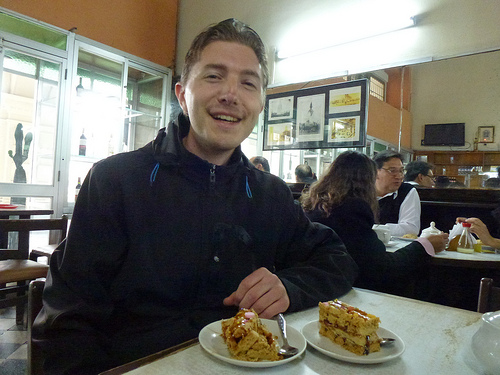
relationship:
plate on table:
[388, 348, 408, 368] [98, 286, 498, 373]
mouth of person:
[207, 108, 245, 125] [27, 19, 355, 375]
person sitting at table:
[97, 25, 332, 294] [397, 296, 442, 342]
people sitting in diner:
[42, 17, 354, 374] [4, 5, 484, 362]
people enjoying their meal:
[298, 149, 449, 278] [195, 296, 400, 374]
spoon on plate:
[274, 312, 298, 358] [195, 313, 305, 367]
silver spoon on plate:
[375, 325, 394, 347] [298, 303, 408, 365]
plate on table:
[195, 313, 305, 367] [98, 286, 498, 373]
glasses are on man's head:
[366, 159, 420, 181] [375, 151, 408, 200]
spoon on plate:
[274, 312, 298, 358] [198, 317, 305, 368]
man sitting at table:
[28, 16, 354, 374] [139, 190, 466, 373]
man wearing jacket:
[25, 16, 364, 371] [33, 108, 360, 373]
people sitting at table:
[298, 149, 449, 278] [404, 223, 498, 289]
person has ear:
[27, 19, 355, 375] [175, 81, 188, 116]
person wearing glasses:
[369, 152, 424, 244] [380, 165, 406, 175]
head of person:
[142, 2, 289, 161] [27, 19, 355, 375]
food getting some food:
[300, 295, 407, 360] [197, 295, 312, 368]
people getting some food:
[245, 147, 495, 269] [197, 295, 312, 368]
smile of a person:
[207, 106, 244, 126] [27, 19, 355, 375]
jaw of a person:
[209, 126, 243, 151] [27, 19, 355, 375]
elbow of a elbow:
[321, 238, 361, 296] [367, 250, 401, 287]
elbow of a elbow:
[321, 238, 361, 296] [394, 220, 421, 237]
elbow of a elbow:
[321, 238, 361, 296] [33, 309, 72, 356]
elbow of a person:
[321, 238, 361, 296] [27, 19, 355, 375]